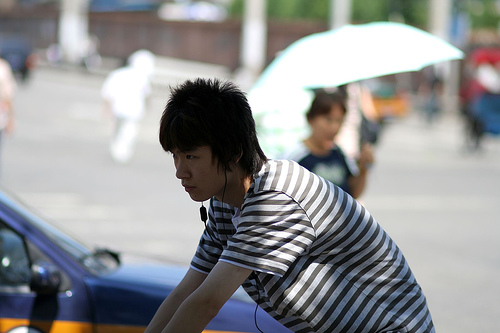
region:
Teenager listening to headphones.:
[117, 59, 278, 269]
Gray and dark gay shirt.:
[177, 126, 487, 331]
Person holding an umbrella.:
[291, 7, 486, 188]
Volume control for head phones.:
[177, 176, 239, 256]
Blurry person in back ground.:
[53, 32, 159, 204]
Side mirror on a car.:
[0, 247, 92, 326]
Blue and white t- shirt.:
[258, 132, 370, 234]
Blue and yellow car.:
[1, 146, 163, 331]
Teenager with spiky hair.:
[19, 77, 460, 325]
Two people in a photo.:
[46, 38, 481, 329]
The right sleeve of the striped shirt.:
[236, 198, 305, 267]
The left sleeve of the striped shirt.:
[188, 213, 215, 275]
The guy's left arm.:
[146, 253, 202, 329]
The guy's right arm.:
[173, 255, 248, 332]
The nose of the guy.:
[173, 164, 194, 180]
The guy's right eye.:
[184, 147, 203, 159]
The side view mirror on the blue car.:
[24, 260, 69, 302]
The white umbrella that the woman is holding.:
[250, 23, 468, 88]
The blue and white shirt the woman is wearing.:
[286, 143, 363, 179]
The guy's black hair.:
[153, 81, 273, 170]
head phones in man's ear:
[195, 136, 237, 228]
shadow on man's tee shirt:
[132, 114, 431, 288]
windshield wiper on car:
[60, 230, 167, 279]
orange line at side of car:
[49, 316, 113, 331]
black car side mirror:
[26, 261, 73, 314]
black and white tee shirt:
[183, 178, 458, 321]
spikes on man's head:
[150, 59, 263, 116]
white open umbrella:
[268, 13, 482, 96]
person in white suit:
[72, 37, 169, 172]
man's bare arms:
[141, 267, 297, 323]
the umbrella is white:
[252, 18, 467, 98]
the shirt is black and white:
[186, 131, 438, 328]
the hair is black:
[156, 61, 258, 186]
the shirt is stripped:
[180, 138, 426, 331]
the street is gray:
[69, 151, 157, 241]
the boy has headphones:
[175, 145, 264, 284]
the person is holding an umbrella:
[229, 15, 456, 189]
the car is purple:
[42, 220, 152, 328]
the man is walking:
[79, 39, 156, 175]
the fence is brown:
[138, 14, 207, 76]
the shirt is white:
[96, 62, 155, 117]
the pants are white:
[96, 107, 148, 170]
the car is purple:
[10, 200, 232, 330]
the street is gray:
[65, 169, 137, 224]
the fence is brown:
[89, 10, 274, 72]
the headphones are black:
[189, 130, 266, 316]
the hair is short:
[131, 65, 272, 169]